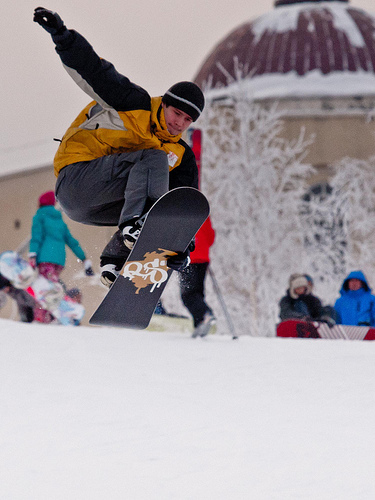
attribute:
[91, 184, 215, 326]
snowboard — black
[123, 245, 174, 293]
logo — brown, white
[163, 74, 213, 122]
cap — black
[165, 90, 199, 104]
stripe — white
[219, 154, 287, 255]
trees — white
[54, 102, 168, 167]
jacket — yellow, black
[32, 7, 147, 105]
arm — extended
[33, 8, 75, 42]
glove — black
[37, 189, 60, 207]
cap — pink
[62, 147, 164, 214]
pants — black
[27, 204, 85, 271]
jacket — aqua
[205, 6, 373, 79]
roof — red, dome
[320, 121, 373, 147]
wall — beige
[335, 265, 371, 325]
jacket — blue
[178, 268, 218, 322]
pants — black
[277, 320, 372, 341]
board — red